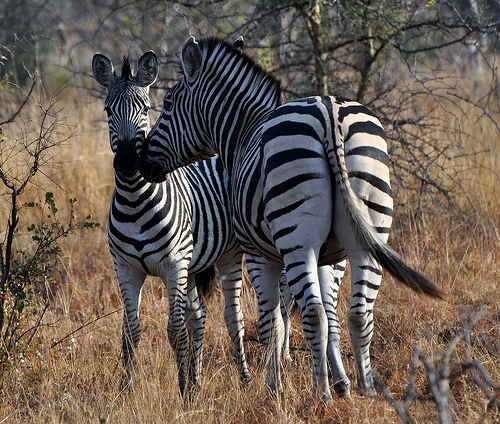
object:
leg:
[285, 266, 329, 409]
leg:
[347, 261, 381, 399]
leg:
[222, 244, 252, 394]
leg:
[243, 252, 284, 404]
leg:
[117, 274, 143, 396]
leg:
[186, 276, 209, 390]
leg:
[164, 280, 190, 406]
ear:
[179, 38, 203, 76]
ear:
[138, 51, 160, 85]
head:
[139, 36, 248, 183]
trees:
[182, 0, 500, 223]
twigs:
[359, 301, 500, 424]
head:
[91, 50, 158, 180]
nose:
[111, 142, 167, 183]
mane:
[196, 35, 291, 105]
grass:
[0, 77, 498, 423]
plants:
[0, 8, 83, 372]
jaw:
[159, 120, 204, 182]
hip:
[255, 96, 396, 206]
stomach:
[237, 211, 276, 259]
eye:
[163, 99, 174, 110]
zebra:
[90, 50, 264, 396]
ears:
[92, 50, 160, 88]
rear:
[259, 85, 396, 401]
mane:
[118, 50, 132, 80]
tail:
[322, 110, 445, 298]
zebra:
[136, 36, 446, 400]